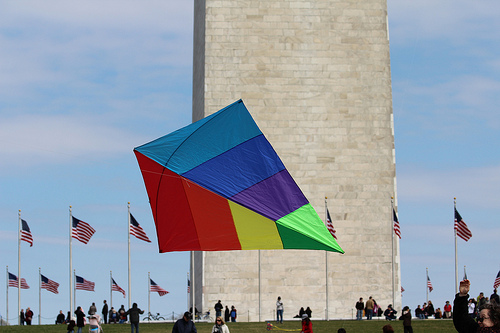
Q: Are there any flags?
A: Yes, there is a flag.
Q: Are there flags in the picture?
A: Yes, there is a flag.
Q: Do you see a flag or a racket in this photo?
A: Yes, there is a flag.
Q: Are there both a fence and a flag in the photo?
A: No, there is a flag but no fences.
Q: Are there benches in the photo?
A: No, there are no benches.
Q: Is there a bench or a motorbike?
A: No, there are no benches or motorcycles.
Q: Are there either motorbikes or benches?
A: No, there are no benches or motorbikes.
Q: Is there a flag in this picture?
A: Yes, there is a flag.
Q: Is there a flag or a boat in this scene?
A: Yes, there is a flag.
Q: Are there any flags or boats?
A: Yes, there is a flag.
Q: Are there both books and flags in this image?
A: No, there is a flag but no books.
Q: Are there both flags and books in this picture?
A: No, there is a flag but no books.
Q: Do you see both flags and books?
A: No, there is a flag but no books.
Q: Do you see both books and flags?
A: No, there is a flag but no books.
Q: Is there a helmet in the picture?
A: No, there are no helmets.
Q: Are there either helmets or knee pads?
A: No, there are no helmets or knee pads.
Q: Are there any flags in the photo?
A: Yes, there is a flag.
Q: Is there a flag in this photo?
A: Yes, there is a flag.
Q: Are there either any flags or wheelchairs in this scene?
A: Yes, there is a flag.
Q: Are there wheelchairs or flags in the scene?
A: Yes, there is a flag.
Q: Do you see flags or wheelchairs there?
A: Yes, there is a flag.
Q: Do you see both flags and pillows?
A: No, there is a flag but no pillows.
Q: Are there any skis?
A: No, there are no skis.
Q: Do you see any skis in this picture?
A: No, there are no skis.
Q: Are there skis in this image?
A: No, there are no skis.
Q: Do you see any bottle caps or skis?
A: No, there are no skis or bottle caps.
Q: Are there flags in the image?
A: Yes, there is a flag.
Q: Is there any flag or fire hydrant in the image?
A: Yes, there is a flag.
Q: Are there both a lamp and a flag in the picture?
A: No, there is a flag but no lamps.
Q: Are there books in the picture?
A: No, there are no books.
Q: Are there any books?
A: No, there are no books.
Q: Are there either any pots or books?
A: No, there are no books or pots.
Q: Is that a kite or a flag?
A: That is a flag.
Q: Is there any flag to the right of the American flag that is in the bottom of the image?
A: Yes, there is a flag to the right of the American flag.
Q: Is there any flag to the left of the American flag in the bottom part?
A: No, the flag is to the right of the American flag.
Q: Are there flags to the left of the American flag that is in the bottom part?
A: No, the flag is to the right of the American flag.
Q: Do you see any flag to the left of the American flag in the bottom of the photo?
A: No, the flag is to the right of the American flag.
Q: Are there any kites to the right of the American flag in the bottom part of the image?
A: No, there is a flag to the right of the American flag.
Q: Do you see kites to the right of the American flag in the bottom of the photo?
A: No, there is a flag to the right of the American flag.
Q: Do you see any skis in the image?
A: No, there are no skis.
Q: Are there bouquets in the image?
A: No, there are no bouquets.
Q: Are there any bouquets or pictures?
A: No, there are no bouquets or pictures.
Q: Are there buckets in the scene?
A: No, there are no buckets.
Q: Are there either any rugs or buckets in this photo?
A: No, there are no buckets or rugs.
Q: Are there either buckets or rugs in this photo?
A: No, there are no buckets or rugs.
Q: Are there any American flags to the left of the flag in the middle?
A: Yes, there is an American flag to the left of the flag.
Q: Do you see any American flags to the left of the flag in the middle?
A: Yes, there is an American flag to the left of the flag.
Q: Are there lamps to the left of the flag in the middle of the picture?
A: No, there is an American flag to the left of the flag.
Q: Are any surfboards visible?
A: No, there are no surfboards.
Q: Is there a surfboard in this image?
A: No, there are no surfboards.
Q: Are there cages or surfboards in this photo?
A: No, there are no surfboards or cages.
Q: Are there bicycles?
A: No, there are no bicycles.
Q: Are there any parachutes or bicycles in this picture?
A: No, there are no bicycles or parachutes.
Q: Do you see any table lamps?
A: No, there are no table lamps.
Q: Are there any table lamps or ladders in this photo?
A: No, there are no table lamps or ladders.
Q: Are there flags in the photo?
A: Yes, there is a flag.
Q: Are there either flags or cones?
A: Yes, there is a flag.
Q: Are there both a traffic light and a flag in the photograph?
A: No, there is a flag but no traffic lights.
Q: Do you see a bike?
A: No, there are no bikes.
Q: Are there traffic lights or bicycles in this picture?
A: No, there are no bicycles or traffic lights.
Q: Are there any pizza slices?
A: No, there are no pizza slices.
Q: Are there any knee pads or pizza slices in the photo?
A: No, there are no pizza slices or knee pads.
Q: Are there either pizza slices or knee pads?
A: No, there are no pizza slices or knee pads.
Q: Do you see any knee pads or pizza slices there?
A: No, there are no pizza slices or knee pads.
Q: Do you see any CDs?
A: No, there are no cds.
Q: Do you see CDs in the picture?
A: No, there are no cds.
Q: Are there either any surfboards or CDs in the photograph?
A: No, there are no CDs or surfboards.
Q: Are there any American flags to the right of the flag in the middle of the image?
A: Yes, there is an American flag to the right of the flag.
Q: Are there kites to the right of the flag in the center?
A: No, there is an American flag to the right of the flag.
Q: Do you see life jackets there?
A: No, there are no life jackets.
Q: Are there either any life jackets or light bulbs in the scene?
A: No, there are no life jackets or light bulbs.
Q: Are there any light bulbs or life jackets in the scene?
A: No, there are no life jackets or light bulbs.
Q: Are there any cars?
A: No, there are no cars.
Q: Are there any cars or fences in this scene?
A: No, there are no cars or fences.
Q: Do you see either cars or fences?
A: No, there are no cars or fences.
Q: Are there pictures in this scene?
A: No, there are no pictures.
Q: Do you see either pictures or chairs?
A: No, there are no pictures or chairs.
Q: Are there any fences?
A: No, there are no fences.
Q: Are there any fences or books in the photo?
A: No, there are no fences or books.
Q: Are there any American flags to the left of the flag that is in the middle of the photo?
A: Yes, there is an American flag to the left of the flag.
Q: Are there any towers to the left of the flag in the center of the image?
A: No, there is an American flag to the left of the flag.